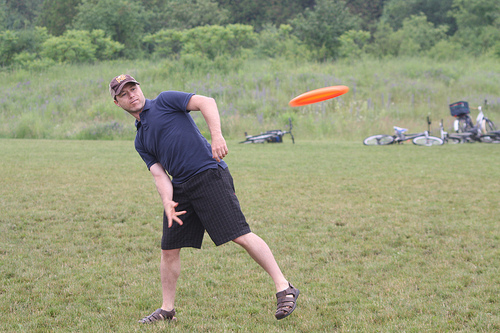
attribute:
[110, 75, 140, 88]
cap — brown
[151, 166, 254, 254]
shorts — black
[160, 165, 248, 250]
shorts — black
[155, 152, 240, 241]
shorts — black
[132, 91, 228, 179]
blue shirt — navy blue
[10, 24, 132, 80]
tree — green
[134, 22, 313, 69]
tree — green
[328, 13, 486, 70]
tree — green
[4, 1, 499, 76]
bush — thick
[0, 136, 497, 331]
grass — field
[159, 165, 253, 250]
black shorts — greyish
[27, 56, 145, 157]
unkept grass — tall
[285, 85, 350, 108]
tenniquoit — orange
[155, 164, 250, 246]
short pants — black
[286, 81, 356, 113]
frisbee — orange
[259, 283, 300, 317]
sandals — brown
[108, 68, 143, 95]
cap — brown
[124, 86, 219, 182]
shirt — blue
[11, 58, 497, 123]
grass — very long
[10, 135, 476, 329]
floor — grass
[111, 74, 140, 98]
hat — brown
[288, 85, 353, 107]
frisbee — round, orange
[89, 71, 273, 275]
man — slanted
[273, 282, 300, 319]
shoe — brown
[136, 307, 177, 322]
shoe — brown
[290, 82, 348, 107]
frisbee — orange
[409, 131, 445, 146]
bicycle wheel — round